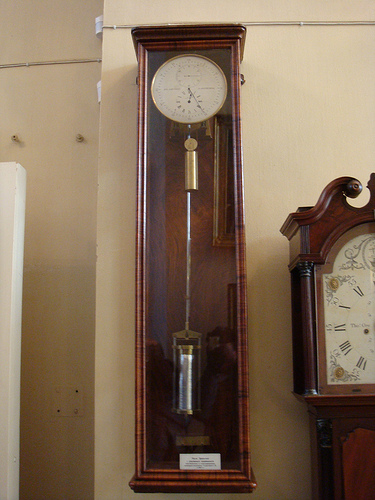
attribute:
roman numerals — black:
[352, 283, 362, 296]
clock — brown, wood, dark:
[278, 173, 373, 498]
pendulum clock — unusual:
[129, 23, 256, 491]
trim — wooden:
[128, 23, 246, 47]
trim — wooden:
[284, 173, 366, 235]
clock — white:
[314, 227, 374, 395]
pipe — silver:
[9, 11, 372, 77]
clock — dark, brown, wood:
[269, 173, 371, 494]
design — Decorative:
[328, 353, 359, 380]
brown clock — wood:
[129, 24, 259, 491]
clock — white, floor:
[126, 13, 264, 496]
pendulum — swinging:
[164, 323, 205, 420]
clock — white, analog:
[148, 50, 231, 123]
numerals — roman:
[327, 275, 374, 370]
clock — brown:
[119, 11, 256, 481]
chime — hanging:
[175, 127, 199, 420]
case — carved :
[279, 165, 373, 498]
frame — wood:
[125, 26, 258, 493]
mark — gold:
[334, 364, 344, 378]